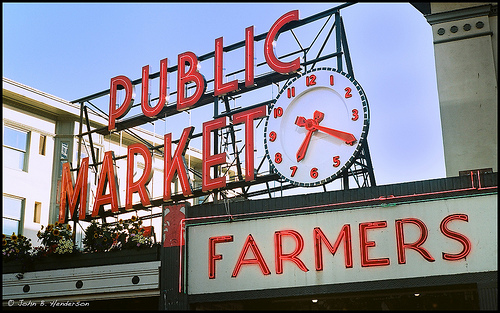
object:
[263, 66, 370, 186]
clock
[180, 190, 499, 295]
sign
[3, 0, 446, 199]
sky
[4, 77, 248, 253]
building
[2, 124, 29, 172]
window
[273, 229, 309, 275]
letter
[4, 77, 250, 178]
roof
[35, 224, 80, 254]
bushes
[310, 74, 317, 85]
numbers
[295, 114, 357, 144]
hand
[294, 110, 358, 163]
seven twenty